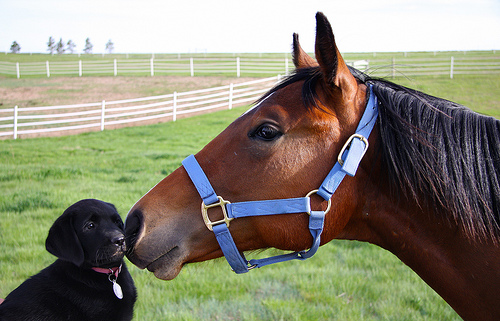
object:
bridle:
[179, 81, 381, 273]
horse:
[121, 10, 500, 321]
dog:
[1, 199, 137, 320]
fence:
[0, 73, 292, 139]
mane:
[249, 64, 499, 246]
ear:
[314, 11, 356, 93]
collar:
[88, 262, 123, 275]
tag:
[110, 281, 124, 299]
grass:
[0, 108, 248, 298]